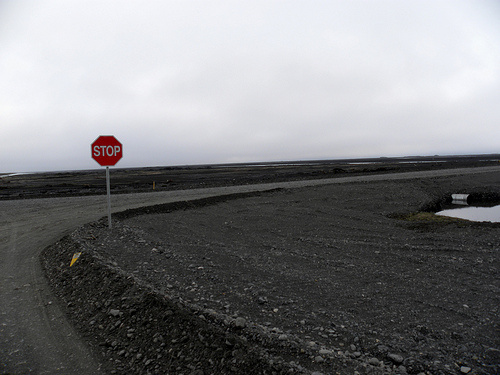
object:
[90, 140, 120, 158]
word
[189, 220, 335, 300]
some dirt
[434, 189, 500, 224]
pond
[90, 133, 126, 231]
stop sign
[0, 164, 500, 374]
road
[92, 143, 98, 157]
lettering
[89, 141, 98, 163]
edge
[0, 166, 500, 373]
ground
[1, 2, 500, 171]
sky